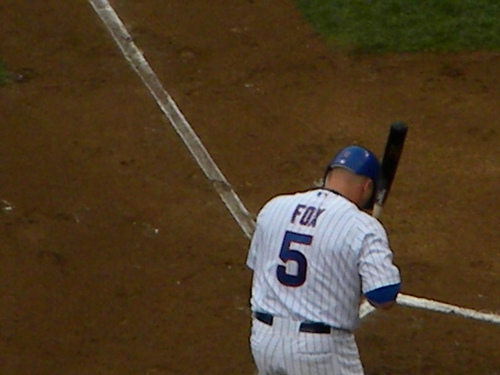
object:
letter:
[291, 203, 308, 224]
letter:
[297, 204, 313, 226]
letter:
[303, 205, 326, 228]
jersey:
[243, 186, 402, 332]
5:
[273, 230, 313, 286]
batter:
[244, 144, 404, 374]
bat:
[367, 120, 411, 220]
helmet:
[326, 145, 382, 181]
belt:
[253, 309, 332, 335]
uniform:
[244, 188, 400, 374]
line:
[89, 0, 258, 243]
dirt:
[0, 0, 499, 374]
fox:
[287, 203, 324, 228]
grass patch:
[296, 0, 497, 58]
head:
[317, 144, 379, 210]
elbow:
[364, 277, 400, 314]